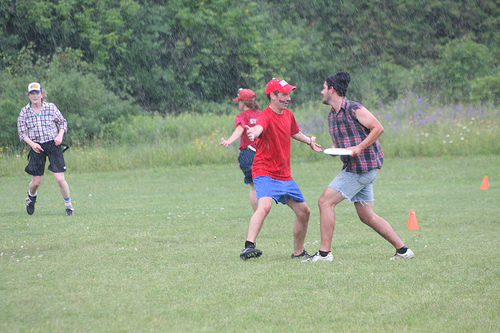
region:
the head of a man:
[262, 70, 302, 117]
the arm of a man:
[252, 105, 277, 140]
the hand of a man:
[240, 119, 260, 146]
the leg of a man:
[241, 173, 276, 243]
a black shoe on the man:
[236, 236, 264, 266]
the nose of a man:
[283, 90, 292, 105]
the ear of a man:
[268, 88, 277, 102]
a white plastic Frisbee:
[318, 140, 358, 161]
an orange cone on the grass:
[401, 200, 423, 237]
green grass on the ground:
[1, 152, 495, 332]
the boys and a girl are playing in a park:
[6, 4, 498, 331]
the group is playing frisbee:
[10, 69, 413, 271]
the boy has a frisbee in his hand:
[313, 67, 386, 179]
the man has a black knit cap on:
[318, 63, 353, 105]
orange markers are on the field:
[402, 165, 492, 232]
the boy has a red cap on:
[262, 75, 296, 112]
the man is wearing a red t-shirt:
[253, 105, 298, 178]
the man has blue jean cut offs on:
[332, 163, 380, 203]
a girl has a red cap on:
[228, 86, 258, 110]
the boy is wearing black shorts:
[23, 142, 65, 176]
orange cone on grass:
[401, 204, 421, 233]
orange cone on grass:
[472, 170, 490, 195]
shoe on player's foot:
[233, 240, 263, 265]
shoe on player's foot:
[284, 245, 309, 257]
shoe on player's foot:
[301, 247, 340, 262]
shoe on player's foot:
[381, 241, 422, 264]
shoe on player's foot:
[63, 205, 83, 220]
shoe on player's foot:
[16, 194, 43, 222]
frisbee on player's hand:
[322, 143, 353, 163]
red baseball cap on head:
[259, 75, 296, 92]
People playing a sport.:
[168, 33, 490, 272]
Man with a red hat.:
[223, 45, 373, 119]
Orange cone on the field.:
[364, 206, 423, 231]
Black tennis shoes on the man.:
[210, 222, 357, 317]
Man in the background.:
[17, 72, 159, 287]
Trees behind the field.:
[152, 47, 374, 187]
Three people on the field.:
[167, 33, 453, 331]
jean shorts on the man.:
[317, 151, 409, 228]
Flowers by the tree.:
[320, 45, 488, 163]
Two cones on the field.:
[363, 142, 493, 275]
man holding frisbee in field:
[306, 70, 414, 263]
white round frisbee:
[322, 145, 348, 155]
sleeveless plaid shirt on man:
[322, 92, 382, 168]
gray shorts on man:
[330, 170, 376, 202]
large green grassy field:
[1, 151, 496, 330]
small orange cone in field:
[405, 205, 417, 230]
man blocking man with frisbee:
[235, 75, 310, 260]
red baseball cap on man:
[265, 72, 295, 89]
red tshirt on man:
[255, 105, 296, 180]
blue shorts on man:
[246, 175, 306, 205]